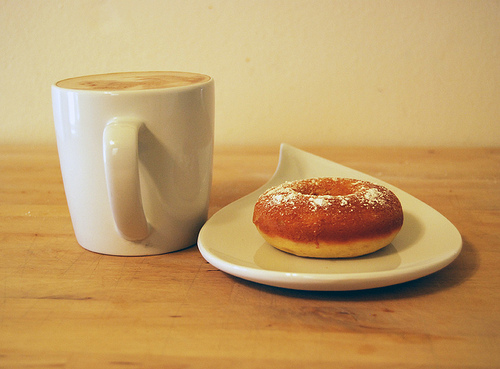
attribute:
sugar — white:
[254, 177, 398, 213]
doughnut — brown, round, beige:
[251, 175, 406, 262]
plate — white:
[196, 140, 466, 294]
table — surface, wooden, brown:
[1, 138, 500, 368]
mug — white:
[49, 69, 217, 258]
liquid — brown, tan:
[55, 70, 213, 92]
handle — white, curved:
[101, 118, 154, 242]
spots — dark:
[169, 305, 395, 321]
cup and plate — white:
[52, 69, 465, 295]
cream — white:
[57, 71, 145, 90]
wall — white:
[1, 0, 499, 144]